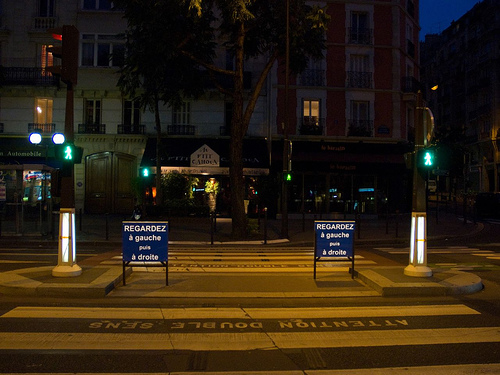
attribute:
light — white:
[407, 207, 434, 265]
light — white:
[195, 179, 219, 197]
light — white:
[202, 177, 216, 192]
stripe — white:
[309, 329, 411, 348]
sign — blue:
[314, 214, 356, 266]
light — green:
[421, 150, 437, 168]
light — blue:
[415, 143, 439, 172]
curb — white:
[390, 284, 433, 295]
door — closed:
[89, 153, 135, 218]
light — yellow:
[202, 177, 215, 188]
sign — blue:
[122, 219, 170, 270]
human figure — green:
[423, 150, 435, 167]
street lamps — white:
[31, 123, 68, 145]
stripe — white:
[116, 300, 373, 320]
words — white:
[168, 311, 416, 329]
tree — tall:
[132, 10, 329, 102]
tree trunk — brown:
[224, 114, 250, 237]